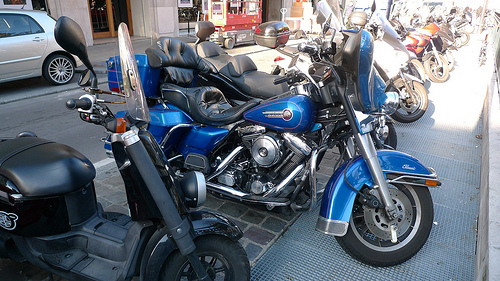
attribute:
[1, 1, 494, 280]
motorcycles — parked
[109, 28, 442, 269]
motorcycle — blue, parked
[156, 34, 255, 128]
seat — black, leather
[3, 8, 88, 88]
car — silver, parked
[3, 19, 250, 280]
scooter — black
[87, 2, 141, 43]
double door — wood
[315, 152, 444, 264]
wheel — black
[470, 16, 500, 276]
wall — white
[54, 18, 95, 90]
side mirror — black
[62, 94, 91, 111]
handle — black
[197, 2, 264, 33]
cart — red